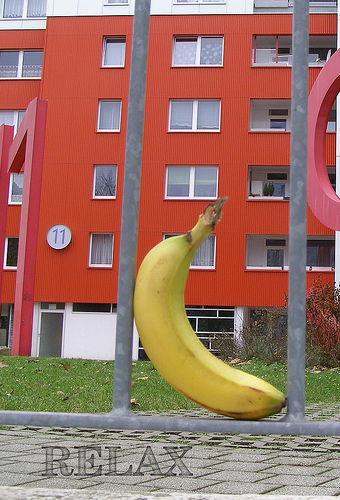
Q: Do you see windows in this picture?
A: Yes, there is a window.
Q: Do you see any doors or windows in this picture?
A: Yes, there is a window.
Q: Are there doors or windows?
A: Yes, there is a window.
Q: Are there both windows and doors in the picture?
A: Yes, there are both a window and a door.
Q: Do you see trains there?
A: No, there are no trains.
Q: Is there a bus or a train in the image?
A: No, there are no trains or buses.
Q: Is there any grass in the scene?
A: Yes, there is grass.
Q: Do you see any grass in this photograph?
A: Yes, there is grass.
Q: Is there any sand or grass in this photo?
A: Yes, there is grass.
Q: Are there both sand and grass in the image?
A: No, there is grass but no sand.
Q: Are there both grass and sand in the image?
A: No, there is grass but no sand.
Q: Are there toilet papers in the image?
A: No, there are no toilet papers.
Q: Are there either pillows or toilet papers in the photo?
A: No, there are no toilet papers or pillows.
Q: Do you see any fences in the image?
A: Yes, there is a fence.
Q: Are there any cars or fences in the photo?
A: Yes, there is a fence.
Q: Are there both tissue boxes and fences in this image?
A: No, there is a fence but no tissue boxes.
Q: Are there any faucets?
A: No, there are no faucets.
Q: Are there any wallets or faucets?
A: No, there are no faucets or wallets.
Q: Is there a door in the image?
A: Yes, there is a door.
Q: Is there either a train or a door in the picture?
A: Yes, there is a door.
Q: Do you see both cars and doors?
A: No, there is a door but no cars.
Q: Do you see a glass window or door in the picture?
A: Yes, there is a glass door.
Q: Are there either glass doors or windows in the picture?
A: Yes, there is a glass door.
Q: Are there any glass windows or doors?
A: Yes, there is a glass door.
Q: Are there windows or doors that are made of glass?
A: Yes, the door is made of glass.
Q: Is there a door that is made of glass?
A: Yes, there is a door that is made of glass.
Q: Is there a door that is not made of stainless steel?
A: Yes, there is a door that is made of glass.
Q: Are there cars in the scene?
A: No, there are no cars.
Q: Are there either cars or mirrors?
A: No, there are no cars or mirrors.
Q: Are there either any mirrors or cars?
A: No, there are no cars or mirrors.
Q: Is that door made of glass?
A: Yes, the door is made of glass.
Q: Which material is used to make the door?
A: The door is made of glass.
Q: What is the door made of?
A: The door is made of glass.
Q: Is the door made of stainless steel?
A: No, the door is made of glass.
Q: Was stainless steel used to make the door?
A: No, the door is made of glass.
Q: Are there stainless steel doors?
A: No, there is a door but it is made of glass.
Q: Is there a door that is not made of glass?
A: No, there is a door but it is made of glass.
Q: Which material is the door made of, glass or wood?
A: The door is made of glass.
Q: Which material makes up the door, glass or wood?
A: The door is made of glass.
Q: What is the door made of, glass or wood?
A: The door is made of glass.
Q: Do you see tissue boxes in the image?
A: No, there are no tissue boxes.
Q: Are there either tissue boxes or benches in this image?
A: No, there are no tissue boxes or benches.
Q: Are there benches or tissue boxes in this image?
A: No, there are no tissue boxes or benches.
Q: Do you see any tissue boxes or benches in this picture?
A: No, there are no tissue boxes or benches.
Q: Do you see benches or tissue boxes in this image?
A: No, there are no tissue boxes or benches.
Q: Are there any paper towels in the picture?
A: No, there are no paper towels.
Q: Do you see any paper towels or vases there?
A: No, there are no paper towels or vases.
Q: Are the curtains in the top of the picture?
A: Yes, the curtains are in the top of the image.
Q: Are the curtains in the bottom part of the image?
A: No, the curtains are in the top of the image.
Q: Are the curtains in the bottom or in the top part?
A: The curtains are in the top of the image.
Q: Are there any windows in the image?
A: Yes, there are windows.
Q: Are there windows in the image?
A: Yes, there are windows.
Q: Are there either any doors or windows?
A: Yes, there are windows.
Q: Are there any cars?
A: No, there are no cars.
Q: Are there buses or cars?
A: No, there are no cars or buses.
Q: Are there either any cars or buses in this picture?
A: No, there are no cars or buses.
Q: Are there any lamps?
A: No, there are no lamps.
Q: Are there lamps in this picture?
A: No, there are no lamps.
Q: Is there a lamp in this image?
A: No, there are no lamps.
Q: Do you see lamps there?
A: No, there are no lamps.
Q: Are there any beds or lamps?
A: No, there are no lamps or beds.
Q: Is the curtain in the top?
A: Yes, the curtain is in the top of the image.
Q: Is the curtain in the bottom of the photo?
A: No, the curtain is in the top of the image.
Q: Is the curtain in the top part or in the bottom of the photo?
A: The curtain is in the top of the image.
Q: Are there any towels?
A: No, there are no towels.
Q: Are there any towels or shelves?
A: No, there are no towels or shelves.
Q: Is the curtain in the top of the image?
A: Yes, the curtain is in the top of the image.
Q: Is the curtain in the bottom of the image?
A: No, the curtain is in the top of the image.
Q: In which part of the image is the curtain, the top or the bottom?
A: The curtain is in the top of the image.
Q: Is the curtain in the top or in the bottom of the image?
A: The curtain is in the top of the image.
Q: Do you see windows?
A: Yes, there is a window.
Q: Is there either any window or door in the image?
A: Yes, there is a window.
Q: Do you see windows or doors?
A: Yes, there is a window.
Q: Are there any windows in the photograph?
A: Yes, there is a window.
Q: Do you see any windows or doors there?
A: Yes, there is a window.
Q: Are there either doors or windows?
A: Yes, there is a window.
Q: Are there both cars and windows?
A: No, there is a window but no cars.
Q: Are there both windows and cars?
A: No, there is a window but no cars.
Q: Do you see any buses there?
A: No, there are no buses.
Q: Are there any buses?
A: No, there are no buses.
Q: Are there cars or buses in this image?
A: No, there are no buses or cars.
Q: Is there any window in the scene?
A: Yes, there is a window.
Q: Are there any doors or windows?
A: Yes, there is a window.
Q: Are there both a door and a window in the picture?
A: Yes, there are both a window and a door.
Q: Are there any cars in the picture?
A: No, there are no cars.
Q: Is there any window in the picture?
A: Yes, there is a window.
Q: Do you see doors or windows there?
A: Yes, there is a window.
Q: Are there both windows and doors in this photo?
A: Yes, there are both a window and a door.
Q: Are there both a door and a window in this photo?
A: Yes, there are both a window and a door.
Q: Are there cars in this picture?
A: No, there are no cars.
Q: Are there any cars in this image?
A: No, there are no cars.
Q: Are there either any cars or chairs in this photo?
A: No, there are no cars or chairs.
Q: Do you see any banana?
A: Yes, there is a banana.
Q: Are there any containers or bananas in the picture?
A: Yes, there is a banana.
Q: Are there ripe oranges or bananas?
A: Yes, there is a ripe banana.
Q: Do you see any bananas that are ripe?
A: Yes, there is a ripe banana.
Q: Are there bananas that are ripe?
A: Yes, there is a banana that is ripe.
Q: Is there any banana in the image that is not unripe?
A: Yes, there is an ripe banana.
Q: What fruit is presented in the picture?
A: The fruit is a banana.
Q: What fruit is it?
A: The fruit is a banana.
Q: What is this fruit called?
A: This is a banana.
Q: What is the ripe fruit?
A: The fruit is a banana.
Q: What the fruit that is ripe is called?
A: The fruit is a banana.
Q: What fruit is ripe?
A: The fruit is a banana.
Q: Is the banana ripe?
A: Yes, the banana is ripe.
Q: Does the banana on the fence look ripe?
A: Yes, the banana is ripe.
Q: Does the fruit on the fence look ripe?
A: Yes, the banana is ripe.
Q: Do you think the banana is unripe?
A: No, the banana is ripe.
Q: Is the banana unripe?
A: No, the banana is ripe.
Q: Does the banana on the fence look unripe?
A: No, the banana is ripe.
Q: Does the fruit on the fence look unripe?
A: No, the banana is ripe.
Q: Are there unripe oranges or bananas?
A: No, there is a banana but it is ripe.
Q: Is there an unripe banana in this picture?
A: No, there is a banana but it is ripe.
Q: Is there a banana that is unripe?
A: No, there is a banana but it is ripe.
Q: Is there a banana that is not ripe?
A: No, there is a banana but it is ripe.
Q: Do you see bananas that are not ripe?
A: No, there is a banana but it is ripe.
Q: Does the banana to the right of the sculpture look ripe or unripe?
A: The banana is ripe.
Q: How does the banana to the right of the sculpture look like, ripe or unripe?
A: The banana is ripe.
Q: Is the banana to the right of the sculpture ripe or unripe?
A: The banana is ripe.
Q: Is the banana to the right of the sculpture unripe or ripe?
A: The banana is ripe.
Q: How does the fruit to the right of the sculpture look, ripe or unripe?
A: The banana is ripe.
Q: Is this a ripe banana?
A: Yes, this is a ripe banana.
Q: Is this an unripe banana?
A: No, this is a ripe banana.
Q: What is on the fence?
A: The banana is on the fence.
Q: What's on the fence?
A: The banana is on the fence.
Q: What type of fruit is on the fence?
A: The fruit is a banana.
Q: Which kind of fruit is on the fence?
A: The fruit is a banana.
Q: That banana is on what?
A: The banana is on the fence.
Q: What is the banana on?
A: The banana is on the fence.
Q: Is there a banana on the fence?
A: Yes, there is a banana on the fence.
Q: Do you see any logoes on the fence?
A: No, there is a banana on the fence.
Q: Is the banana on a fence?
A: Yes, the banana is on a fence.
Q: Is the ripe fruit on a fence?
A: Yes, the banana is on a fence.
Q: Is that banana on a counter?
A: No, the banana is on a fence.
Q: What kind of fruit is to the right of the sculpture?
A: The fruit is a banana.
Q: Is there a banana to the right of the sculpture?
A: Yes, there is a banana to the right of the sculpture.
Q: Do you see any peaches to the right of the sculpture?
A: No, there is a banana to the right of the sculpture.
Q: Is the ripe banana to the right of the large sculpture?
A: Yes, the banana is to the right of the sculpture.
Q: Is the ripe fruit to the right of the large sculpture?
A: Yes, the banana is to the right of the sculpture.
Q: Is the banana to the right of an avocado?
A: No, the banana is to the right of the sculpture.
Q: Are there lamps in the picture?
A: No, there are no lamps.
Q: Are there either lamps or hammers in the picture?
A: No, there are no lamps or hammers.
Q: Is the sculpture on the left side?
A: Yes, the sculpture is on the left of the image.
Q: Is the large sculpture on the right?
A: No, the sculpture is on the left of the image.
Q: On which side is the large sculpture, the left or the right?
A: The sculpture is on the left of the image.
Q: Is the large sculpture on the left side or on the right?
A: The sculpture is on the left of the image.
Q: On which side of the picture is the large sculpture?
A: The sculpture is on the left of the image.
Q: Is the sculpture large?
A: Yes, the sculpture is large.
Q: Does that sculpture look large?
A: Yes, the sculpture is large.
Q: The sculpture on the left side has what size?
A: The sculpture is large.